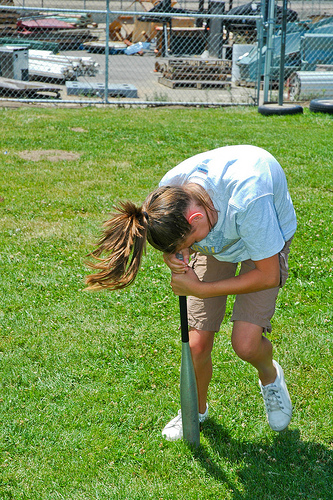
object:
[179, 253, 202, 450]
baseball bat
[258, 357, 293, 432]
shoe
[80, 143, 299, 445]
woman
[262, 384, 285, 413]
shoestring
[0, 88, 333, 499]
grass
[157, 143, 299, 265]
shirt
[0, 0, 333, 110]
fence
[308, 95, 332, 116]
tire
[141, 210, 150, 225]
rubber band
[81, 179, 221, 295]
hair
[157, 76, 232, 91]
pallets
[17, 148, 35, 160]
patch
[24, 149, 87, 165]
dirt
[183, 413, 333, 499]
shadow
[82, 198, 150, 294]
ponytail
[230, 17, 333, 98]
trash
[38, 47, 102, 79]
metal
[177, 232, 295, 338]
brown shorts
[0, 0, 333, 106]
ground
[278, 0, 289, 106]
pole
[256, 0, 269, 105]
gate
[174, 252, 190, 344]
handle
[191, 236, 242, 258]
design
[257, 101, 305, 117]
tires